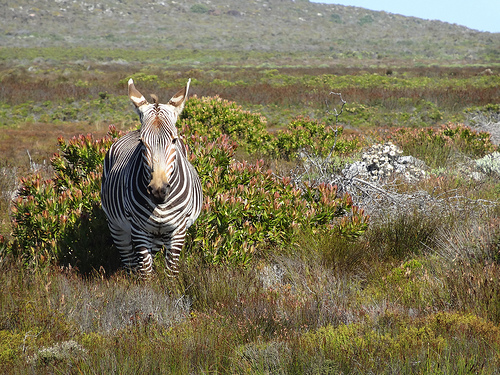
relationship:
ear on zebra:
[122, 74, 149, 108] [97, 71, 207, 280]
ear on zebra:
[167, 71, 194, 116] [97, 71, 207, 280]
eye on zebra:
[135, 136, 148, 150] [97, 71, 207, 280]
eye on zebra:
[172, 137, 178, 144] [97, 71, 207, 280]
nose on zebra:
[147, 183, 170, 201] [97, 71, 207, 280]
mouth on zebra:
[140, 188, 172, 204] [97, 71, 207, 280]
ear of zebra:
[168, 77, 192, 113] [97, 71, 207, 280]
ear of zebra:
[127, 78, 148, 109] [91, 61, 213, 276]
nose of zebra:
[147, 183, 170, 201] [101, 70, 211, 272]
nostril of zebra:
[141, 174, 171, 206] [97, 67, 218, 290]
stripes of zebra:
[112, 150, 162, 224] [97, 71, 207, 280]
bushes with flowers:
[204, 93, 359, 252] [219, 104, 294, 171]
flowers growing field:
[220, 136, 354, 250] [7, 39, 473, 340]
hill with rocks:
[8, 1, 478, 72] [314, 146, 451, 195]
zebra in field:
[92, 71, 210, 296] [5, 1, 472, 122]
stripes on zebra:
[167, 197, 192, 230] [83, 66, 203, 280]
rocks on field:
[326, 140, 427, 207] [7, 39, 473, 340]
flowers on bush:
[6, 93, 494, 262] [217, 161, 372, 298]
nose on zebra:
[146, 173, 169, 204] [87, 70, 207, 285]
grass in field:
[244, 223, 405, 353] [14, 49, 483, 353]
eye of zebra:
[140, 135, 177, 149] [91, 61, 213, 276]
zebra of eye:
[100, 77, 205, 284] [139, 129, 179, 150]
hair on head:
[150, 109, 165, 122] [117, 61, 201, 197]